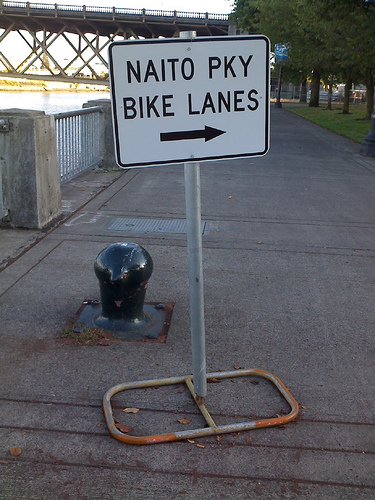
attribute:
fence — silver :
[53, 99, 103, 178]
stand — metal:
[185, 163, 208, 312]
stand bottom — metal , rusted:
[96, 365, 302, 445]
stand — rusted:
[101, 364, 299, 451]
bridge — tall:
[26, 28, 93, 79]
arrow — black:
[158, 118, 230, 146]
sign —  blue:
[272, 40, 289, 63]